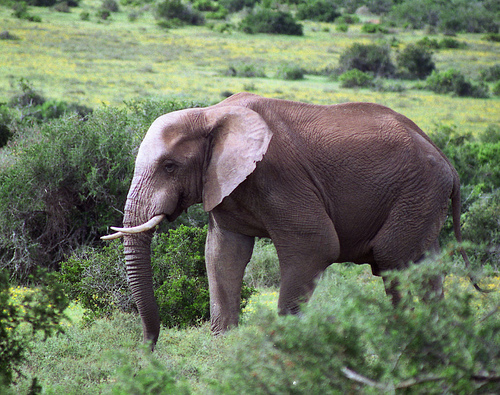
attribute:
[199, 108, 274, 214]
ear — large, gray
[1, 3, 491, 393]
field — large, open, small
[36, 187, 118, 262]
branch — wood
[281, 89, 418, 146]
back — gray, wrinkly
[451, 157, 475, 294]
tail — long, gray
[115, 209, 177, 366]
elephant trunk — long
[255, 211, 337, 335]
leg — gray, wrinkly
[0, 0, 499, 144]
field — green, yellow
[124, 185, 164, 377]
elephant trunk — wrinkly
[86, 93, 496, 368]
elephant — grey, brown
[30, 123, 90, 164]
leaves — green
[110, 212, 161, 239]
tusk — long, gray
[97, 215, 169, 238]
tusks — small, white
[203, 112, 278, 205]
ear — big, flat, grey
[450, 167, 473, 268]
tail — long, thin